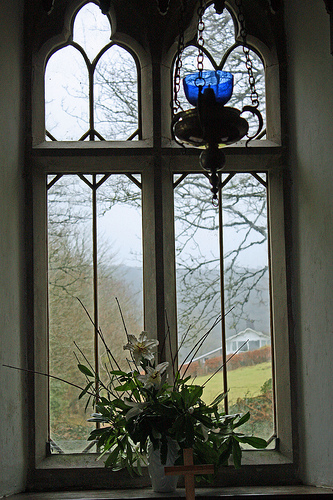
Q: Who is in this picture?
A: Noone.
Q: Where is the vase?
A: Behind cross.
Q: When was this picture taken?
A: Daytime.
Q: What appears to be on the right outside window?
A: House.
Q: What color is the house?
A: White.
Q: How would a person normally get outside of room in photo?
A: Door.